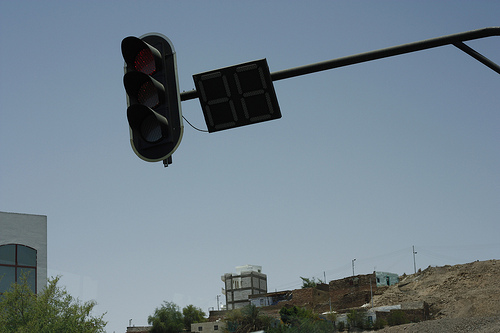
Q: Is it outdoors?
A: Yes, it is outdoors.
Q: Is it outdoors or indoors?
A: It is outdoors.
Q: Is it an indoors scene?
A: No, it is outdoors.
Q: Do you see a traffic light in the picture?
A: Yes, there is a traffic light.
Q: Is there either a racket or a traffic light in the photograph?
A: Yes, there is a traffic light.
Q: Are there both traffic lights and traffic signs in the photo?
A: No, there is a traffic light but no traffic signs.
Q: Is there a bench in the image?
A: No, there are no benches.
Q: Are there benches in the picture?
A: No, there are no benches.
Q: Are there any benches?
A: No, there are no benches.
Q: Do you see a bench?
A: No, there are no benches.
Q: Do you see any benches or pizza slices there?
A: No, there are no benches or pizza slices.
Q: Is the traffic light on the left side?
A: Yes, the traffic light is on the left of the image.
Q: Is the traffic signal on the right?
A: No, the traffic signal is on the left of the image.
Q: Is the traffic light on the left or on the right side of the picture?
A: The traffic light is on the left of the image.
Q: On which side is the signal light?
A: The signal light is on the left of the image.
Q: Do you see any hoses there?
A: No, there are no hoses.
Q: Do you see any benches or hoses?
A: No, there are no hoses or benches.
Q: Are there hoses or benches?
A: No, there are no hoses or benches.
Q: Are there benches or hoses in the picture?
A: No, there are no hoses or benches.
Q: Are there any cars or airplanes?
A: No, there are no cars or airplanes.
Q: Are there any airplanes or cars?
A: No, there are no cars or airplanes.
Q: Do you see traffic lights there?
A: Yes, there is a traffic light.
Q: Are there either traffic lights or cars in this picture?
A: Yes, there is a traffic light.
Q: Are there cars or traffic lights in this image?
A: Yes, there is a traffic light.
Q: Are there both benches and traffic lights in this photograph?
A: No, there is a traffic light but no benches.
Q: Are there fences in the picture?
A: No, there are no fences.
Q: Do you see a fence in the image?
A: No, there are no fences.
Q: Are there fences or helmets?
A: No, there are no fences or helmets.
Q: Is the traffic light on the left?
A: Yes, the traffic light is on the left of the image.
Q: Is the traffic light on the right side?
A: No, the traffic light is on the left of the image.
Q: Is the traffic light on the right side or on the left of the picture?
A: The traffic light is on the left of the image.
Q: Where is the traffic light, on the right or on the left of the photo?
A: The traffic light is on the left of the image.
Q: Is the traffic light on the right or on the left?
A: The traffic light is on the left of the image.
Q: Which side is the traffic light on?
A: The traffic light is on the left of the image.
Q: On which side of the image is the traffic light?
A: The traffic light is on the left of the image.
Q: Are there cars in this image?
A: No, there are no cars.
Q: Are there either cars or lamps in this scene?
A: No, there are no cars or lamps.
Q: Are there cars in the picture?
A: No, there are no cars.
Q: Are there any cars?
A: No, there are no cars.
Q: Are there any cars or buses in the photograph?
A: No, there are no cars or buses.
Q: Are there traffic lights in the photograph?
A: Yes, there is a traffic light.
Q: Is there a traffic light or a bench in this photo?
A: Yes, there is a traffic light.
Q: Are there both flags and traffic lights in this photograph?
A: No, there is a traffic light but no flags.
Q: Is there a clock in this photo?
A: No, there are no clocks.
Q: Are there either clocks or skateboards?
A: No, there are no clocks or skateboards.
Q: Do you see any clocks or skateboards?
A: No, there are no clocks or skateboards.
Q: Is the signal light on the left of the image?
A: Yes, the signal light is on the left of the image.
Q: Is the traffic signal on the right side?
A: No, the traffic signal is on the left of the image.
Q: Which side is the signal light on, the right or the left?
A: The signal light is on the left of the image.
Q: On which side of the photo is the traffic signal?
A: The traffic signal is on the left of the image.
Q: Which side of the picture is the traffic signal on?
A: The traffic signal is on the left of the image.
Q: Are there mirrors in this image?
A: No, there are no mirrors.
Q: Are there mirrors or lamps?
A: No, there are no mirrors or lamps.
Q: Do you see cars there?
A: No, there are no cars.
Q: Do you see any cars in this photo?
A: No, there are no cars.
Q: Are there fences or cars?
A: No, there are no cars or fences.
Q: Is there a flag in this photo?
A: No, there are no flags.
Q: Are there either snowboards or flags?
A: No, there are no flags or snowboards.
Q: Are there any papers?
A: No, there are no papers.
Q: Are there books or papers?
A: No, there are no papers or books.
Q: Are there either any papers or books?
A: No, there are no papers or books.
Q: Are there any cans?
A: No, there are no cans.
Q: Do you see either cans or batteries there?
A: No, there are no cans or batteries.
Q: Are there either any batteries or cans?
A: No, there are no cans or batteries.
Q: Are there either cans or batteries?
A: No, there are no cans or batteries.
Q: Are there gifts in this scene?
A: No, there are no gifts.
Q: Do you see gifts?
A: No, there are no gifts.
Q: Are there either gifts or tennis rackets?
A: No, there are no gifts or tennis rackets.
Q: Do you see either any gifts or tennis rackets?
A: No, there are no gifts or tennis rackets.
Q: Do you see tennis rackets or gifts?
A: No, there are no gifts or tennis rackets.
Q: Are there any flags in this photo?
A: No, there are no flags.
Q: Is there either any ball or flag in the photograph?
A: No, there are no flags or balls.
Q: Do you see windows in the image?
A: Yes, there is a window.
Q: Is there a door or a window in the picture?
A: Yes, there is a window.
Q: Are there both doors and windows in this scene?
A: No, there is a window but no doors.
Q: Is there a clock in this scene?
A: No, there are no clocks.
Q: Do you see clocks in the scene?
A: No, there are no clocks.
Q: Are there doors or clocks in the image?
A: No, there are no clocks or doors.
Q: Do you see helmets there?
A: No, there are no helmets.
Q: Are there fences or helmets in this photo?
A: No, there are no helmets or fences.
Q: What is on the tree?
A: The leaves are on the tree.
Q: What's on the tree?
A: The leaves are on the tree.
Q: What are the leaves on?
A: The leaves are on the tree.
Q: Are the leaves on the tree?
A: Yes, the leaves are on the tree.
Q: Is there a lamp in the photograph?
A: No, there are no lamps.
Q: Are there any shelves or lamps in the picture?
A: No, there are no lamps or shelves.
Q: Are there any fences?
A: No, there are no fences.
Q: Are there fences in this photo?
A: No, there are no fences.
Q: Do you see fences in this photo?
A: No, there are no fences.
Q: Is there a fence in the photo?
A: No, there are no fences.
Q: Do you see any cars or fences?
A: No, there are no fences or cars.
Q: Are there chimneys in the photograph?
A: No, there are no chimneys.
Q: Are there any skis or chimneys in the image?
A: No, there are no chimneys or skis.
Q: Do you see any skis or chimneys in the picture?
A: No, there are no chimneys or skis.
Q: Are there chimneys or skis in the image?
A: No, there are no chimneys or skis.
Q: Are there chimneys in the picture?
A: No, there are no chimneys.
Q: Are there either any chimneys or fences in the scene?
A: No, there are no chimneys or fences.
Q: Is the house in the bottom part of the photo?
A: Yes, the house is in the bottom of the image.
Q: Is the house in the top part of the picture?
A: No, the house is in the bottom of the image.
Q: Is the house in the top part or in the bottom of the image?
A: The house is in the bottom of the image.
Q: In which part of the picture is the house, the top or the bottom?
A: The house is in the bottom of the image.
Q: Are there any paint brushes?
A: No, there are no paint brushes.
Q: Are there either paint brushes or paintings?
A: No, there are no paint brushes or paintings.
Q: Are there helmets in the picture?
A: No, there are no helmets.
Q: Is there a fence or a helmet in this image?
A: No, there are no helmets or fences.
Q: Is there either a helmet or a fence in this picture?
A: No, there are no helmets or fences.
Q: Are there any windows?
A: Yes, there is a window.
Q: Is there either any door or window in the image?
A: Yes, there is a window.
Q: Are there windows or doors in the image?
A: Yes, there is a window.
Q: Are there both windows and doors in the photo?
A: No, there is a window but no doors.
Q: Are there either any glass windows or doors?
A: Yes, there is a glass window.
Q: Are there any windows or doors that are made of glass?
A: Yes, the window is made of glass.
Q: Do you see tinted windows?
A: Yes, there is a tinted window.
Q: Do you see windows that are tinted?
A: Yes, there is a window that is tinted.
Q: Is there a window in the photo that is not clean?
A: Yes, there is a tinted window.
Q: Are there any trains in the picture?
A: No, there are no trains.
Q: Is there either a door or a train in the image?
A: No, there are no trains or doors.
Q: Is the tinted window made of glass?
A: Yes, the window is made of glass.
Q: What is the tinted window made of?
A: The window is made of glass.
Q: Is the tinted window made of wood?
A: No, the window is made of glass.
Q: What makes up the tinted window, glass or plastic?
A: The window is made of glass.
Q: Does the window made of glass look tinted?
A: Yes, the window is tinted.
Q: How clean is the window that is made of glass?
A: The window is tinted.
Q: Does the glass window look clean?
A: No, the window is tinted.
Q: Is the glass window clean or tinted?
A: The window is tinted.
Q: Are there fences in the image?
A: No, there are no fences.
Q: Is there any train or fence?
A: No, there are no fences or trains.